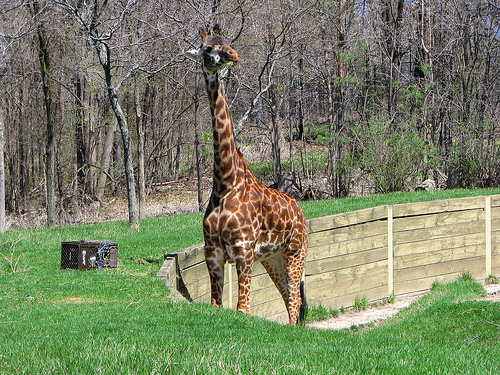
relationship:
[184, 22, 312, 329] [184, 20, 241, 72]
giraffe has head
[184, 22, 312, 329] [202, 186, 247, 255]
giraffe has chest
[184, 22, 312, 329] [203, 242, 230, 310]
giraffe has leg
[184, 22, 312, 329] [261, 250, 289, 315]
giraffe has leg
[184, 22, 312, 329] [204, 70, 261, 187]
giraffe has neck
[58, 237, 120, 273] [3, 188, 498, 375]
milk crate on ground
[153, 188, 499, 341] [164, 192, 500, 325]
enclosure made of wooden boards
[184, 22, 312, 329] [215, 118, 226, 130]
giraffe has spot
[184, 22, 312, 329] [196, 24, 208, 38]
giraffe has horn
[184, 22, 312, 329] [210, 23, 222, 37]
giraffe has horn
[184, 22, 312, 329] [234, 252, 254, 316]
giraffe has leg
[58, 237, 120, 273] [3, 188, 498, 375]
crate on grass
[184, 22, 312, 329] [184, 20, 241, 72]
giraffe has dark head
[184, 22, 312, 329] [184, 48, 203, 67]
giraffe has ear